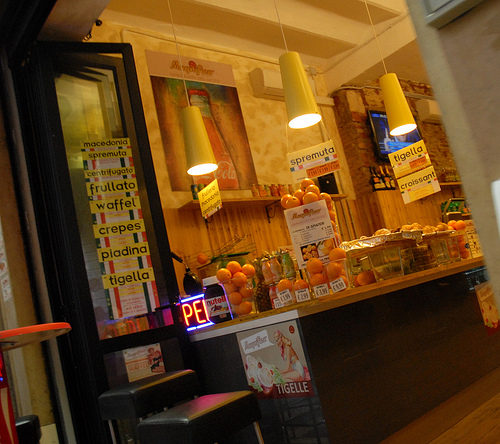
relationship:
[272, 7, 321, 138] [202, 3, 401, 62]
lights hanging from ceiling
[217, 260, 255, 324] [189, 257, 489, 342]
oranges in a counter on counter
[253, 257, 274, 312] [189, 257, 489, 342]
pineapple sitting on counter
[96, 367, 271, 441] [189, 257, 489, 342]
two stools placed next to counter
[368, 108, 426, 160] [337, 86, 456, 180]
tv mounted on building wall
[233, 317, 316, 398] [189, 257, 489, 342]
advertisement sign displayed on side of counter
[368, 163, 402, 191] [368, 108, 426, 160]
liquor bottles are on shelf below tv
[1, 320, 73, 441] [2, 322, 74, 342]
table has a red edge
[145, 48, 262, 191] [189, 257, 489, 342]
picture on wall behind counter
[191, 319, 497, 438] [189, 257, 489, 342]
wood base supports counter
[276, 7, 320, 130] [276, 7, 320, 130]
lights hanging lights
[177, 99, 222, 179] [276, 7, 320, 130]
left hanging lights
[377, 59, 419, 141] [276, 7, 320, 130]
right hanging lights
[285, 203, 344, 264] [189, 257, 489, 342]
poster colored redwhite on counter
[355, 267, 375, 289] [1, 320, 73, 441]
an orange on top of a table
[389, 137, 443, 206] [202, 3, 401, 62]
sign hangs from ceiling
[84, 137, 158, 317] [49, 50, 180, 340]
sticker words are on a glass plain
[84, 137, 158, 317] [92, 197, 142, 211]
sticker words showing waffel in black and yellow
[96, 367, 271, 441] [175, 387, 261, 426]
two stools are covered in leather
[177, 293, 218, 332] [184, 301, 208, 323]
light up neon sign displaying letters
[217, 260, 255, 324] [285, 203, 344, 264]
oranges in a pile sign or poster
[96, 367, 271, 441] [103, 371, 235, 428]
two stools with black seats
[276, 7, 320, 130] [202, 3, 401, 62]
lights suspended from ceiling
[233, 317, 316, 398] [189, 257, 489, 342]
advertisement sign under top of counter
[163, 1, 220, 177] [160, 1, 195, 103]
long modern light hanging from a cable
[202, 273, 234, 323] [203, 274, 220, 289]
jar with a white lid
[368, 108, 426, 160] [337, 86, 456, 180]
tv flatscreen mountd on building wall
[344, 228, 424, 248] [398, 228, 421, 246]
tray made of tin foil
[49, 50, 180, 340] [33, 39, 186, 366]
window of an open door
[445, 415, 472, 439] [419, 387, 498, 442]
section part of floor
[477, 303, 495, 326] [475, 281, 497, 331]
part of a banner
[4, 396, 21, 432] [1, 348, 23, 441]
an edge of a table post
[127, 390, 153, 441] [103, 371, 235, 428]
edge of seats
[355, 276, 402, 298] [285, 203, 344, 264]
part of poster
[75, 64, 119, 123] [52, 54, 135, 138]
part of glass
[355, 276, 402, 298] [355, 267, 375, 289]
part of an orange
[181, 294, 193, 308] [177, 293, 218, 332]
part of a light up neon sign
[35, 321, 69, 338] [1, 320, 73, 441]
edge of a table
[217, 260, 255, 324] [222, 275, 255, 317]
oranges are in a glass pitcher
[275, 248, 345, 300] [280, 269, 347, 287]
sereral oranges are in glasses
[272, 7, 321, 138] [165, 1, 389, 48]
lights made of yellow metal are suspended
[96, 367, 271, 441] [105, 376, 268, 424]
two stools has dark cushions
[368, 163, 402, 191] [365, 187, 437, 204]
liquor bottles are on a shelf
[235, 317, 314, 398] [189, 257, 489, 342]
advertisement sign of a woman beneath counter